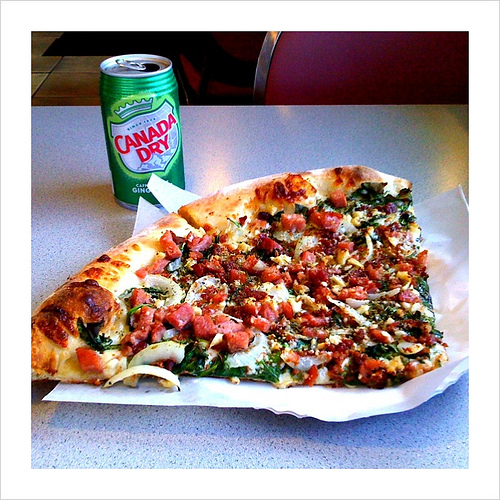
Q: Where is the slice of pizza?
A: On the paper.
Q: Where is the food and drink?
A: On the table.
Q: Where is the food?
A: On the white and black table.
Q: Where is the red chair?
A: At the table.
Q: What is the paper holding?
A: A slice of pizza.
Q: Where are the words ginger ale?
A: On the green can.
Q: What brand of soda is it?
A: Canada Dry.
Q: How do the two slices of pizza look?
A: Large.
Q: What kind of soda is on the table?
A: Canada Dry.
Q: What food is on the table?
A: Pizza.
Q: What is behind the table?
A: A red chair with a silver frame.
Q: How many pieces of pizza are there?
A: There are two slices of pizza.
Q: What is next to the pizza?
A: Its a green can.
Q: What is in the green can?
A: Its canada dry ginger ale.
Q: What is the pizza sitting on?
A: A white table with speckles.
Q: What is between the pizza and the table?
A: A white paper.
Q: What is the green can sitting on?
A: It is sitting on the table.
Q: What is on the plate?
A: Two slices of a pizza.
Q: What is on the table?
A: Slizes of pizza on a plate.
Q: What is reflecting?
A: Reflection of light on table.